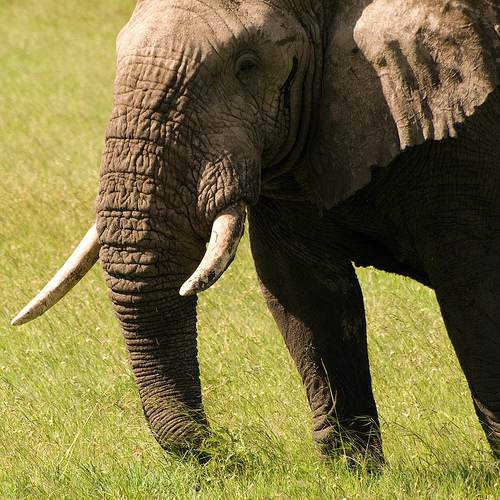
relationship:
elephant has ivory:
[8, 1, 496, 468] [13, 208, 255, 319]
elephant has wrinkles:
[8, 1, 496, 468] [117, 165, 168, 339]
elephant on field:
[8, 1, 496, 468] [12, 356, 435, 482]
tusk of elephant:
[17, 210, 99, 332] [8, 1, 496, 468]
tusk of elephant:
[184, 204, 248, 298] [8, 1, 496, 468]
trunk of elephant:
[99, 158, 215, 454] [8, 1, 496, 468]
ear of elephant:
[321, 5, 497, 206] [8, 1, 496, 468]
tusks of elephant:
[13, 208, 255, 319] [8, 1, 496, 468]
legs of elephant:
[258, 261, 498, 470] [8, 1, 496, 468]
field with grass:
[12, 356, 435, 482] [15, 462, 375, 500]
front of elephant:
[105, 4, 471, 424] [8, 1, 496, 468]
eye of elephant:
[225, 47, 264, 89] [8, 1, 496, 468]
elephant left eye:
[8, 1, 496, 468] [225, 47, 264, 89]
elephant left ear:
[8, 1, 496, 468] [321, 5, 497, 206]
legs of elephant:
[253, 238, 388, 475] [8, 1, 496, 468]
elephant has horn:
[8, 1, 496, 468] [184, 204, 248, 298]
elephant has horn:
[8, 1, 496, 468] [17, 210, 99, 332]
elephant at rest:
[8, 1, 496, 468] [84, 5, 488, 395]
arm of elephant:
[421, 256, 496, 465] [8, 1, 496, 468]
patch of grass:
[237, 414, 304, 491] [15, 462, 375, 500]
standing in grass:
[169, 39, 486, 467] [15, 462, 375, 500]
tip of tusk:
[12, 290, 46, 334] [17, 210, 99, 332]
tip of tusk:
[175, 256, 215, 298] [184, 204, 248, 298]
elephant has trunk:
[8, 1, 496, 468] [99, 158, 215, 454]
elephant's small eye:
[8, 1, 496, 468] [225, 47, 264, 89]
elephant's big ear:
[8, 1, 496, 468] [321, 5, 497, 206]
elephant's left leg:
[8, 1, 496, 468] [421, 256, 496, 465]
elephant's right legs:
[8, 1, 496, 468] [253, 238, 388, 475]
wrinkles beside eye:
[234, 85, 283, 140] [225, 47, 264, 89]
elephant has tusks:
[8, 1, 496, 468] [13, 208, 255, 319]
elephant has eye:
[8, 1, 496, 468] [225, 47, 264, 89]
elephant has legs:
[8, 1, 496, 468] [258, 261, 498, 470]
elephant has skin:
[8, 1, 496, 468] [124, 124, 201, 248]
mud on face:
[269, 17, 303, 62] [127, 8, 314, 212]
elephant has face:
[8, 1, 496, 468] [127, 8, 314, 212]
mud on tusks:
[228, 196, 255, 263] [13, 208, 255, 319]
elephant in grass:
[8, 1, 496, 468] [15, 462, 375, 500]